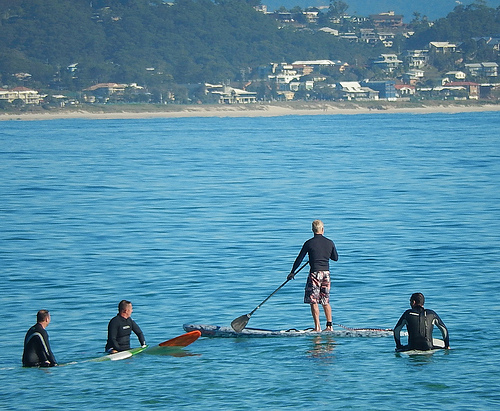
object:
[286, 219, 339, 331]
man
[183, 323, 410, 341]
surfboard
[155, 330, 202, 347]
surfboard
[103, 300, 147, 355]
men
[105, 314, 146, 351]
wetsuit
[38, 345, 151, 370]
surfboard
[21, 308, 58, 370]
man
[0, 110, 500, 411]
water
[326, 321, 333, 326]
strap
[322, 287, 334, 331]
leg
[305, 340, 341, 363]
reflection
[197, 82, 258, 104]
buildings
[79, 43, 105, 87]
trees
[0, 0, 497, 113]
background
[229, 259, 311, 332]
oar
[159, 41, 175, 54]
leaves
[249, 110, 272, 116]
sand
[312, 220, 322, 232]
hair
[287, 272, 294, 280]
hand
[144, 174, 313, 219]
ripples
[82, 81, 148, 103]
houses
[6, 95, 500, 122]
land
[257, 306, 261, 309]
stripe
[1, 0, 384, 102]
forest